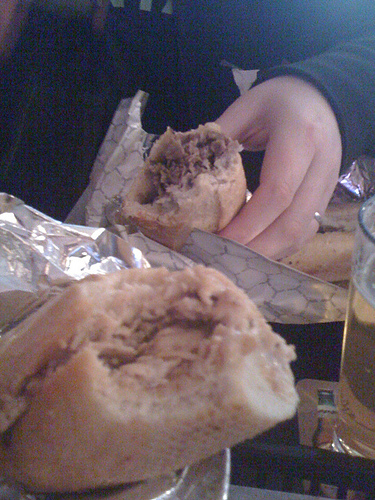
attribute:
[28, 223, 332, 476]
sandwich — bitten, beef, bit, eaten, meat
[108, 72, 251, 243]
hand — human, grabbing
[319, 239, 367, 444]
liquid — golden, yellow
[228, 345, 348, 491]
basket — sort, holding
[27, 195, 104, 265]
foil — holding, that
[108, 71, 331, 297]
person — holding, wearing, black, shirt, hand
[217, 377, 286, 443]
breadh — brown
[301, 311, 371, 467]
cup — glass, brown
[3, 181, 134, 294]
wrapper — silver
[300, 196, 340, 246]
ring — silver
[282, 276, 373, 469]
mug — beer, bottle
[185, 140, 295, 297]
finger — that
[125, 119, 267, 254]
humberger — that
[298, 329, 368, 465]
juice — that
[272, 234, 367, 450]
glass — tall, sit